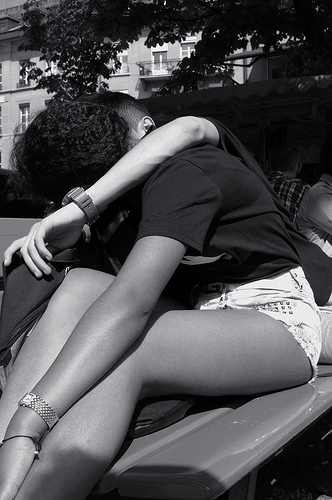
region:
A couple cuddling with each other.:
[2, 77, 331, 499]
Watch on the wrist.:
[55, 183, 101, 228]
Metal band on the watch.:
[15, 390, 59, 430]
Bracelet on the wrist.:
[1, 425, 44, 461]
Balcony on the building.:
[135, 44, 185, 82]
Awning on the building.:
[220, 34, 330, 65]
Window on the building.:
[16, 99, 34, 135]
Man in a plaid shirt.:
[258, 133, 317, 221]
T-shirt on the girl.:
[6, 93, 308, 293]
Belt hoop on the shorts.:
[282, 263, 307, 295]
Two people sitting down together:
[13, 59, 324, 496]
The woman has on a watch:
[13, 388, 63, 433]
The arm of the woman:
[33, 222, 188, 406]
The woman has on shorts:
[190, 260, 326, 383]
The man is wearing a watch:
[51, 179, 103, 223]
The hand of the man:
[1, 199, 90, 276]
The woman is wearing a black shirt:
[130, 143, 307, 287]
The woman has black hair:
[5, 93, 129, 191]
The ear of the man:
[137, 113, 156, 136]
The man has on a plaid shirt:
[262, 169, 311, 223]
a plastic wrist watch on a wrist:
[62, 187, 99, 226]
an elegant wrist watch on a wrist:
[17, 392, 58, 427]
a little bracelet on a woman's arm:
[0, 433, 43, 458]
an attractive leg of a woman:
[14, 307, 310, 499]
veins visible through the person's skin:
[139, 150, 176, 166]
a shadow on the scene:
[25, 447, 227, 499]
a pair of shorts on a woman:
[190, 262, 323, 381]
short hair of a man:
[81, 89, 154, 131]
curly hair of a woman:
[8, 100, 128, 201]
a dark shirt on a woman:
[106, 141, 301, 310]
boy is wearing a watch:
[49, 178, 118, 255]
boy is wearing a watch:
[58, 189, 106, 240]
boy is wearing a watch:
[37, 179, 106, 245]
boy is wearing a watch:
[46, 174, 111, 244]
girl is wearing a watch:
[2, 380, 87, 438]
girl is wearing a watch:
[9, 386, 66, 437]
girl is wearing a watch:
[5, 386, 79, 447]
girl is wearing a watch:
[10, 385, 71, 452]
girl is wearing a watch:
[9, 386, 51, 430]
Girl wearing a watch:
[17, 382, 62, 428]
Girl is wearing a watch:
[15, 388, 63, 432]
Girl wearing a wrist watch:
[16, 389, 60, 431]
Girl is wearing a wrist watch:
[15, 388, 61, 434]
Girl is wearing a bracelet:
[0, 428, 43, 457]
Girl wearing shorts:
[162, 263, 328, 385]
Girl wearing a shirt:
[101, 148, 305, 285]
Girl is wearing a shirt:
[99, 140, 312, 297]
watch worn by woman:
[57, 187, 92, 219]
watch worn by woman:
[22, 390, 68, 434]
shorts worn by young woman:
[212, 263, 327, 390]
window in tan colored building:
[149, 45, 171, 82]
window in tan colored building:
[17, 56, 33, 84]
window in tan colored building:
[38, 56, 56, 74]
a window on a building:
[14, 59, 27, 83]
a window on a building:
[47, 57, 55, 74]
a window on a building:
[112, 54, 128, 72]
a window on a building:
[153, 49, 167, 69]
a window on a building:
[180, 39, 198, 62]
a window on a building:
[19, 105, 26, 129]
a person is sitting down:
[4, 68, 323, 497]